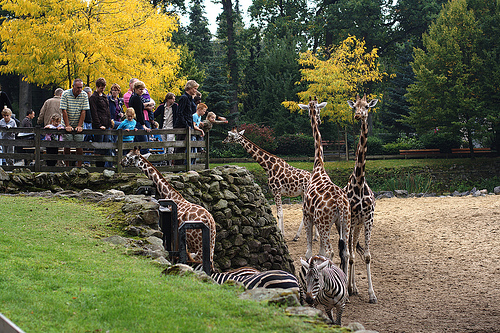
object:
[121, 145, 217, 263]
giraffe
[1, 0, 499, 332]
zoo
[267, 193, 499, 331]
dirt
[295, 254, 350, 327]
giraffe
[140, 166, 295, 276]
wall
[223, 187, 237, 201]
stone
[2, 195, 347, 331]
grass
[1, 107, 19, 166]
people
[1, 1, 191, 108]
trees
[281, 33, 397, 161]
trees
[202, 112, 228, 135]
girl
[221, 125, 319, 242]
giraffe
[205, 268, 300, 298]
zebra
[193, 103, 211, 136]
man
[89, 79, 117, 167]
man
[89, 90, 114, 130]
shirt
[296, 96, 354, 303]
giraffes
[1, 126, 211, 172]
fence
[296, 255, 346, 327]
zebras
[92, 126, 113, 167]
jeans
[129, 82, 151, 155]
man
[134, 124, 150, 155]
jeans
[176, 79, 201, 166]
man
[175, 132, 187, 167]
jeans